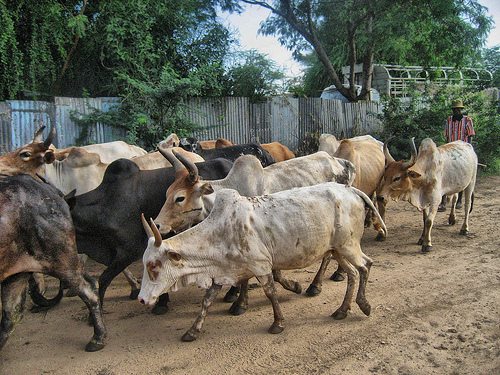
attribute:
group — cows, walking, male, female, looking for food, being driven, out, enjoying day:
[1, 122, 487, 354]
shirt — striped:
[445, 114, 476, 148]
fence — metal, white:
[1, 92, 500, 210]